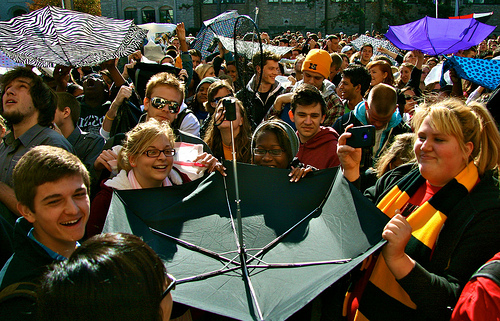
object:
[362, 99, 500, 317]
woman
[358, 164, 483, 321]
scarf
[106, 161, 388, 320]
umbrella